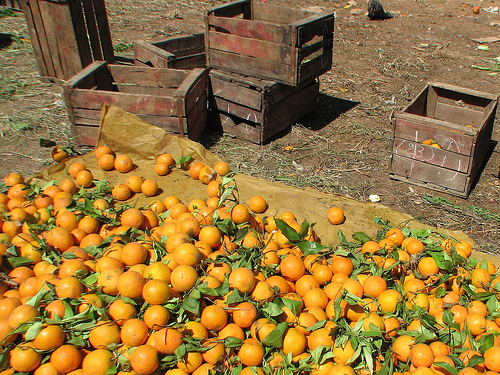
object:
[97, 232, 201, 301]
batch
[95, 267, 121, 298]
oranges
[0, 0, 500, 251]
grass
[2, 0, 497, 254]
ground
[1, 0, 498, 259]
dirt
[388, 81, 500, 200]
crates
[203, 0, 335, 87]
crates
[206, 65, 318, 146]
crates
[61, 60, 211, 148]
crates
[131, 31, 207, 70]
crates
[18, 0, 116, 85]
crates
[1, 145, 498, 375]
leaves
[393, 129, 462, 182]
writing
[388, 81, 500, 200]
box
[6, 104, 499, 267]
bag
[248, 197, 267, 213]
orange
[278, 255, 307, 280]
orange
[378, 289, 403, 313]
orange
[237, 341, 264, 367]
orange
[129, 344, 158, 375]
orange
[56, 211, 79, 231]
oranges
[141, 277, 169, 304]
oranges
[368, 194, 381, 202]
debri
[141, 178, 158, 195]
orange fruit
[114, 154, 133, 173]
orange fruit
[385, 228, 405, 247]
orange fruit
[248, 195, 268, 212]
orange fruit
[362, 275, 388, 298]
orange fruit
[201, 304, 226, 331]
oranges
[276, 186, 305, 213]
brown paper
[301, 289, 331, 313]
oranges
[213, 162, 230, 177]
oranges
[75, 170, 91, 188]
oranges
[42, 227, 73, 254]
oranges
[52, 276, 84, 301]
oranges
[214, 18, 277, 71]
number sign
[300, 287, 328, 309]
oranges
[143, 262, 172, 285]
oranges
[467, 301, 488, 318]
oranges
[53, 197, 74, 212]
oranges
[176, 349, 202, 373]
oranges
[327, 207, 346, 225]
orange fruit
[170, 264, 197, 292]
orange fruit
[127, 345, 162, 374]
orange fruit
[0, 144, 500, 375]
fruit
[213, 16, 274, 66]
markings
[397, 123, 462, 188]
markings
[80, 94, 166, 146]
markings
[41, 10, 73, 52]
markings